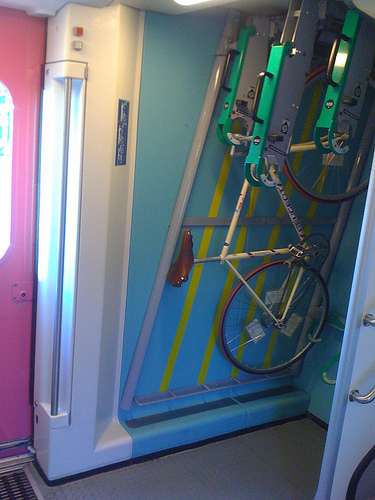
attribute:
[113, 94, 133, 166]
sign — blue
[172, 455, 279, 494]
floor — grey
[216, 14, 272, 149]
bike rack — metal